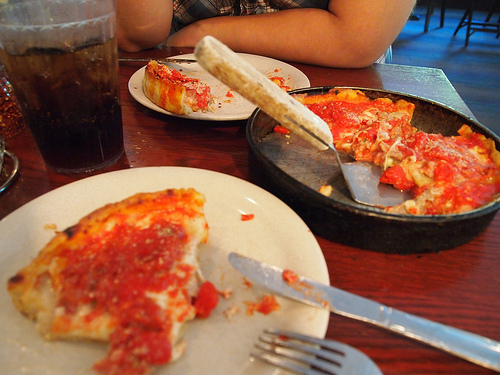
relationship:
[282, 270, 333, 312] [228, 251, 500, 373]
sauce on knife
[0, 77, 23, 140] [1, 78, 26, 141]
container contains red pepper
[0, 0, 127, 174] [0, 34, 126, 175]
glass contains liquid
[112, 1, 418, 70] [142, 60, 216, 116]
man eating pizza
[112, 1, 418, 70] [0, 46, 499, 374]
man at table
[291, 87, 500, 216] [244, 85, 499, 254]
pizza in pan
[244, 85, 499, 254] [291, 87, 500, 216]
pan beneath pizza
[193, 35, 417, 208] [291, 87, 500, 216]
spatula inside pizza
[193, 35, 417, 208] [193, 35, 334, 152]
spatula has handle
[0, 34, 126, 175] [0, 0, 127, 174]
liquid in glass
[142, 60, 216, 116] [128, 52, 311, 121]
pizza on top of plate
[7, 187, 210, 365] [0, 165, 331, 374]
pizza on top of plate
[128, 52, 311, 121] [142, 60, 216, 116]
plate underneath pizza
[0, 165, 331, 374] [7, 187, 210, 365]
plate underneath pizza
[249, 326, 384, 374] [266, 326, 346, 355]
fork has tine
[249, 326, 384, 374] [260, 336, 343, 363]
fork has tine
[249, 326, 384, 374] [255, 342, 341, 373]
fork has tine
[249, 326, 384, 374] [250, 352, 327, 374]
fork has tine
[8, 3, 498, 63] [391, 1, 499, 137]
building has floor